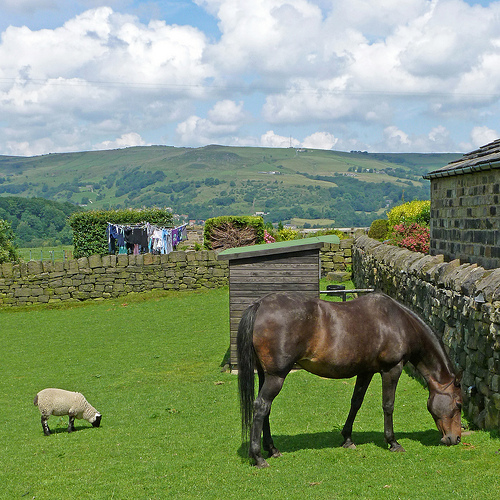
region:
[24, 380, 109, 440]
small white sheep in a field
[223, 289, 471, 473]
black horse in a field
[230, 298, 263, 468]
long black tail of a horse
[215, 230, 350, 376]
small shed with a green roof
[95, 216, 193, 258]
clothes line with many clothes on it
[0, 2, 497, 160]
sky is blue with a lot of clouds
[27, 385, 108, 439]
sheep is eating grass in the field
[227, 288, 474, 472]
horse is eating grass in the field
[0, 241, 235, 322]
a long wall made of stones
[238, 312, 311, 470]
hind leg of a black horse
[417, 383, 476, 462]
head of horse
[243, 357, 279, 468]
leg of horse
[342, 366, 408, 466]
the legs of a horse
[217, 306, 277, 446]
tail of a horse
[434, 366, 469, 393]
ears of a horse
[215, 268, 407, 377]
body of a horse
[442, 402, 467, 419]
eye of a horse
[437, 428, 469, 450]
mouth of a horse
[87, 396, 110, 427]
head of a sheep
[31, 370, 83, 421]
the body of a sheep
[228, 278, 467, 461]
the horse is grazing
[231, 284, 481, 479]
the horse is brown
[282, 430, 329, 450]
shadow is on the ground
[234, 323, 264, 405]
the tail is black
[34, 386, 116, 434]
the sheep is grazing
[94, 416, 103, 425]
the face is black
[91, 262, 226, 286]
the wall is mad of stones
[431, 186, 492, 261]
the wall is made of stones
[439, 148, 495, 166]
the roof is grey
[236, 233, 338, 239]
the roof is green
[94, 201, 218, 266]
clothes drying on the line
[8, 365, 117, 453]
small sheep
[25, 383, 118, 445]
sheep has all it's wool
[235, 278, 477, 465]
dark brown horse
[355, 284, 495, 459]
horse eating grass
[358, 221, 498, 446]
stone wall between the house and the animals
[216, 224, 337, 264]
green roof on top of shelter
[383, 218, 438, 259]
red flowers by the fence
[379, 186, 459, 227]
yellow flowers above the red flowers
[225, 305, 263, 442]
horse has a long black tail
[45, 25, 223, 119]
big white fluffy clouds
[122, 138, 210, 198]
mountains in the distance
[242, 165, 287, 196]
small tree shrubs in the distance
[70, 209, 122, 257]
a tall green tree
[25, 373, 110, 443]
a small sheep grazing for grass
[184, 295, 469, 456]
a big brown horse grazing for grass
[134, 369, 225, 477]
thick and luscious green grass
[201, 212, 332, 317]
a small wooden shed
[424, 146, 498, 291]
a big brick house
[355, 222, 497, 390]
a gate made out of brick